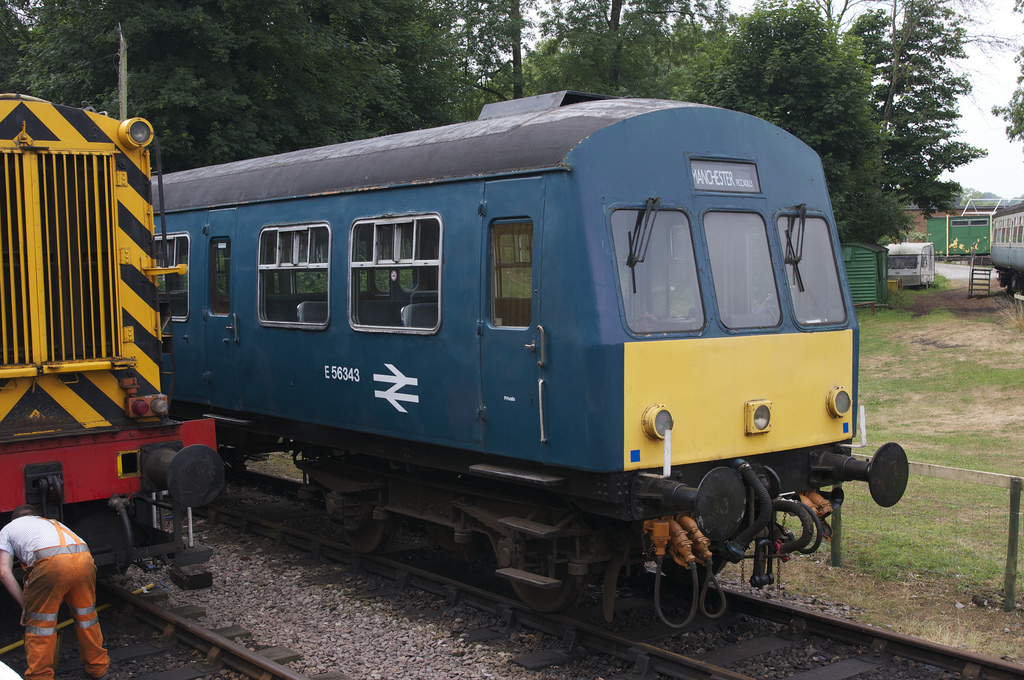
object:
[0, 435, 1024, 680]
train track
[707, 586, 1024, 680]
metal rail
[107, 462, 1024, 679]
metal rail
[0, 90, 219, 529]
train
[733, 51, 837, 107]
leaves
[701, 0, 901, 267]
tree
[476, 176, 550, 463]
door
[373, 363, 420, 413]
emblem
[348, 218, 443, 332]
window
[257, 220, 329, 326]
window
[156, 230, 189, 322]
window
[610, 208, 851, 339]
windshield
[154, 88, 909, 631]
train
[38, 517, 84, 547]
suspenders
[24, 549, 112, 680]
pants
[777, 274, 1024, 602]
grass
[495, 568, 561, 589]
step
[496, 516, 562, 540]
step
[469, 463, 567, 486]
step